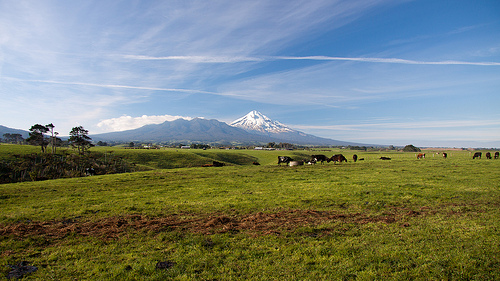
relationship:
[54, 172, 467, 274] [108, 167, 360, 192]
landscape covered grass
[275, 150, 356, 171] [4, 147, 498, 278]
cows grazing on grass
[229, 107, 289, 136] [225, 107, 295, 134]
snow on mountain top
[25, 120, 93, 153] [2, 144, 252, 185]
trees on hill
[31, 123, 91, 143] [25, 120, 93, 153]
leaves on trees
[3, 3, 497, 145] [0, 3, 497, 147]
clouds in sky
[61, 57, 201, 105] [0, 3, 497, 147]
cloud on sky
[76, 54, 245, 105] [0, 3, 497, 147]
cloud on sky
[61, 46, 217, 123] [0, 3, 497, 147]
cloud on sky